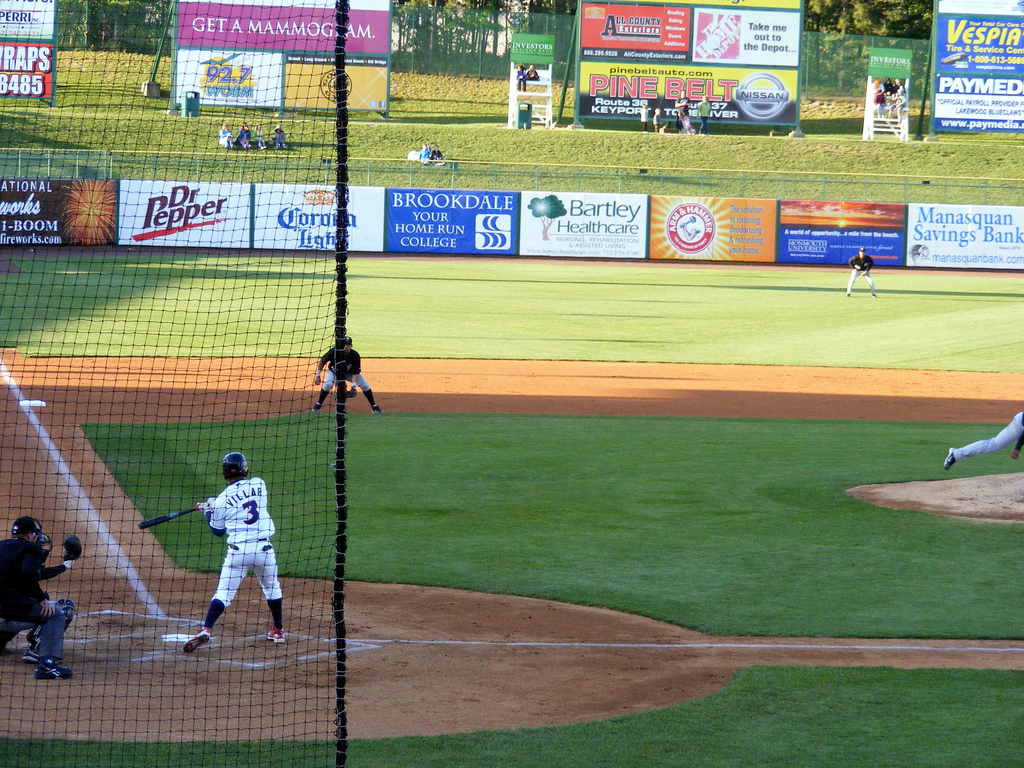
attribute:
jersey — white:
[208, 477, 276, 544]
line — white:
[375, 636, 1023, 653]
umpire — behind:
[3, 515, 92, 683]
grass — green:
[2, 250, 1023, 356]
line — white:
[393, 626, 697, 664]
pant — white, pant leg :
[943, 396, 1020, 501]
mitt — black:
[54, 529, 92, 571]